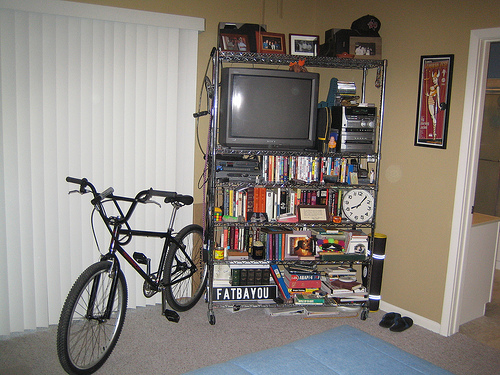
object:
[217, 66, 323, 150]
tv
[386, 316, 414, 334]
shoes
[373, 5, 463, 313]
wall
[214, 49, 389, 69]
frames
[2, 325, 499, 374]
carpet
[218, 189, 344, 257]
window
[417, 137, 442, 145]
ground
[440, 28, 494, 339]
doorframe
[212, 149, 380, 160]
shelf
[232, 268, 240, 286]
books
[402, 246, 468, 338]
frame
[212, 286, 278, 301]
sign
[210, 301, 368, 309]
shelf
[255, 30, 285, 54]
picture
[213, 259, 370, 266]
shelf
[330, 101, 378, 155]
silver stereo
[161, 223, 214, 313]
wheels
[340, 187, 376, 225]
clock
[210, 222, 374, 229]
shelf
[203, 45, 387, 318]
bookcase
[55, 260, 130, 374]
wheel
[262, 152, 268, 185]
dvds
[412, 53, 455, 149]
painting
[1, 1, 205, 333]
blinds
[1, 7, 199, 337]
window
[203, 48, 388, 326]
stand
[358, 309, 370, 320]
wheel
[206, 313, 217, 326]
wheel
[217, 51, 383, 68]
shelf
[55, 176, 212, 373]
bicycle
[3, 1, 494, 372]
room